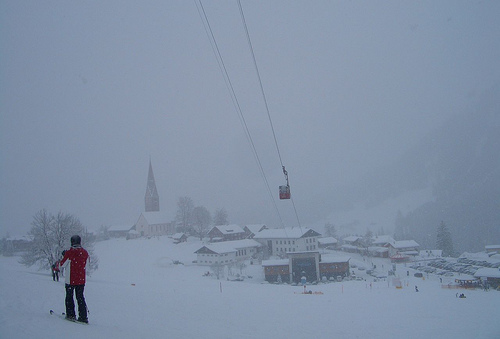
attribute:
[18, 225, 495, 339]
snow — white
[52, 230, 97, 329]
person — skiing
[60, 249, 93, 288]
jacket — warm, red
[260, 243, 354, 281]
building — Snowy, tall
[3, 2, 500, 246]
sky — blue, gray, clear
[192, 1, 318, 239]
power lines — Black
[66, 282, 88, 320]
pants — black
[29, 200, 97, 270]
tree — bare, Snowy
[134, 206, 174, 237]
church — Snowy